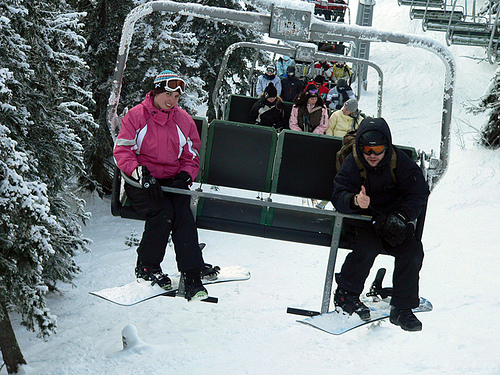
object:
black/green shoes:
[181, 273, 210, 304]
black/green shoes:
[131, 260, 173, 292]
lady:
[110, 67, 223, 300]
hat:
[150, 67, 189, 92]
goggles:
[359, 144, 386, 158]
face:
[362, 145, 385, 167]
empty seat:
[196, 115, 280, 240]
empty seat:
[263, 127, 345, 247]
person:
[256, 64, 284, 99]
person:
[280, 67, 307, 99]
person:
[306, 75, 333, 105]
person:
[326, 77, 355, 107]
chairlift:
[210, 41, 391, 148]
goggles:
[156, 76, 191, 97]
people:
[329, 116, 423, 331]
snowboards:
[292, 289, 435, 337]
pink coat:
[290, 100, 330, 135]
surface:
[140, 289, 270, 373]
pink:
[146, 131, 176, 159]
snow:
[8, 162, 45, 214]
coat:
[112, 92, 205, 185]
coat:
[247, 94, 287, 129]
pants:
[122, 176, 207, 273]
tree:
[66, 0, 213, 198]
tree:
[188, 0, 276, 122]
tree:
[466, 69, 500, 150]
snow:
[2, 0, 500, 373]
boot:
[388, 305, 424, 332]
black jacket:
[330, 146, 431, 222]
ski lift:
[86, 0, 457, 339]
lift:
[102, 0, 456, 337]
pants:
[335, 204, 424, 310]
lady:
[323, 95, 367, 148]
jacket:
[322, 110, 364, 138]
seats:
[333, 141, 431, 258]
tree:
[0, 0, 96, 374]